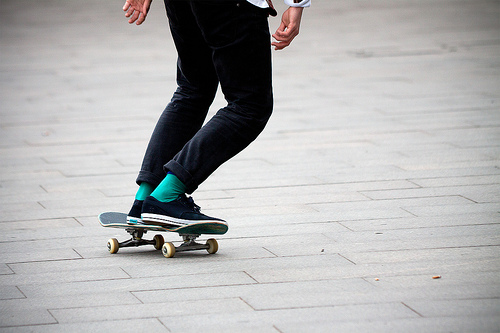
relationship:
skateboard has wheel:
[91, 206, 230, 247] [162, 243, 180, 257]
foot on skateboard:
[126, 203, 226, 224] [91, 206, 230, 247]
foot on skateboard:
[131, 203, 147, 224] [91, 206, 230, 247]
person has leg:
[121, 0, 315, 208] [188, 14, 275, 199]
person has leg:
[121, 0, 315, 208] [120, 20, 204, 198]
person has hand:
[121, 0, 315, 208] [270, 5, 316, 47]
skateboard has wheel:
[91, 206, 230, 247] [204, 235, 216, 260]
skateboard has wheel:
[91, 206, 230, 247] [104, 235, 122, 250]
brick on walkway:
[17, 259, 125, 266] [5, 1, 482, 332]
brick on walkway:
[17, 259, 125, 266] [3, 4, 483, 64]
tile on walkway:
[28, 122, 106, 143] [3, 4, 483, 64]